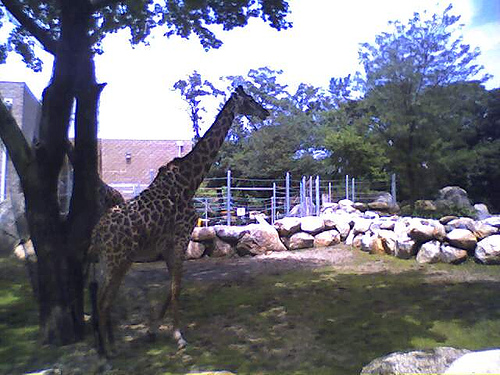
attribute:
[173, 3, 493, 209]
trees — bunched, behind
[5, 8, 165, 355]
tree — large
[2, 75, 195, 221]
building — brick, large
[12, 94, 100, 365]
tree trunk — intertwining